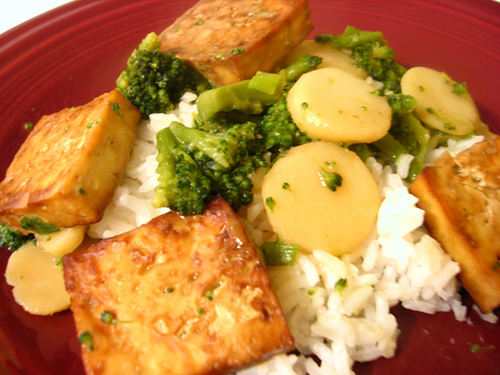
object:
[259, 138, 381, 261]
potato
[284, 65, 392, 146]
potato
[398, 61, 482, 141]
potato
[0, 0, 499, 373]
food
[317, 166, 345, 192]
broccoli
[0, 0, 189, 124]
grooves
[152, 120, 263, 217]
broccoli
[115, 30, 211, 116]
broccoli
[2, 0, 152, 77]
lines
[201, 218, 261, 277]
browning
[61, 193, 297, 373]
tofu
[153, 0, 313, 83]
tofu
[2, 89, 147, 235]
tofu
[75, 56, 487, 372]
rice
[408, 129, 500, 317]
tofu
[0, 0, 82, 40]
edge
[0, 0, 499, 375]
dish